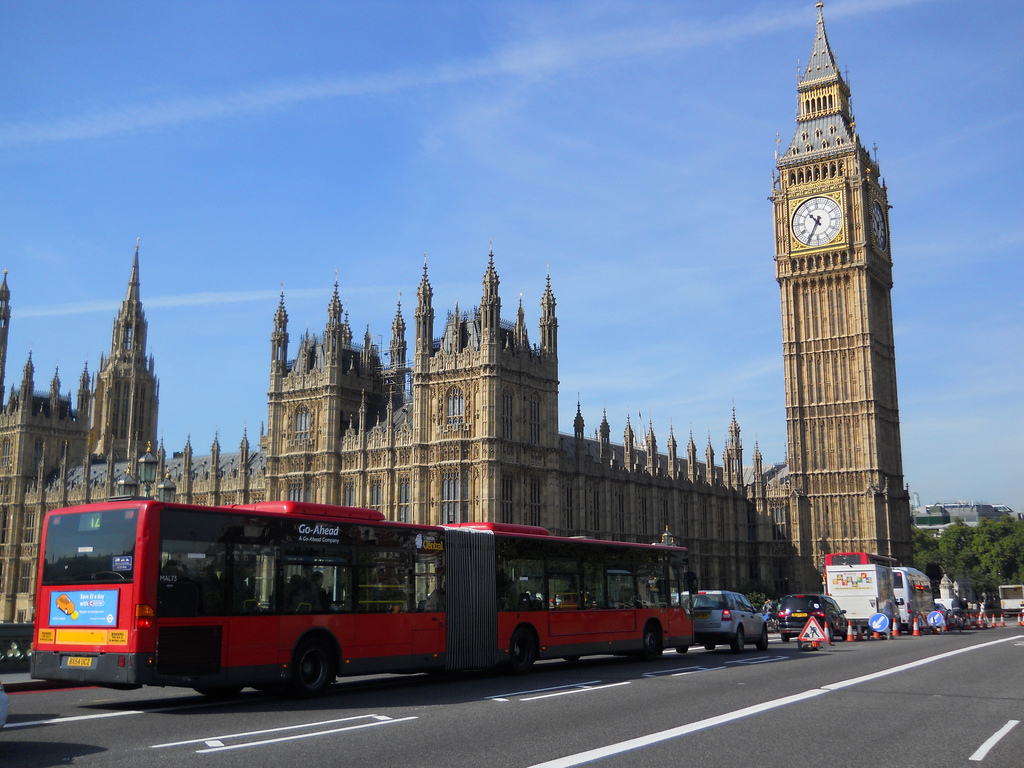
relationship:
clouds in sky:
[123, 80, 392, 164] [234, 124, 374, 213]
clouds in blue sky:
[6, 3, 1016, 500] [0, 0, 1024, 514]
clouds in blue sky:
[116, 65, 616, 202] [0, 0, 1024, 514]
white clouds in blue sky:
[396, 48, 665, 214] [5, 4, 287, 92]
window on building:
[496, 467, 517, 521] [1, 10, 922, 611]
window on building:
[487, 377, 516, 436] [1, 10, 922, 611]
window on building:
[385, 455, 418, 514] [1, 10, 922, 611]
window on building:
[360, 468, 383, 508] [1, 10, 922, 611]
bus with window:
[28, 499, 694, 696] [153, 512, 682, 646]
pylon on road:
[904, 613, 920, 642] [7, 609, 1013, 766]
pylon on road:
[886, 611, 903, 643] [7, 609, 1013, 766]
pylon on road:
[863, 614, 886, 649] [7, 609, 1013, 766]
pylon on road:
[835, 611, 867, 646] [7, 609, 1013, 766]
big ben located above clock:
[774, 4, 905, 567] [796, 185, 859, 263]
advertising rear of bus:
[39, 582, 131, 631] [28, 499, 694, 696]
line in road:
[951, 707, 1016, 766] [0, 621, 1024, 768]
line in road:
[546, 629, 1019, 766] [0, 621, 1024, 768]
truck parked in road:
[823, 543, 916, 624] [0, 621, 1024, 768]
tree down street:
[917, 496, 1022, 594] [0, 537, 1016, 766]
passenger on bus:
[273, 570, 302, 613] [28, 499, 694, 696]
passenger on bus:
[303, 566, 330, 611] [28, 499, 694, 696]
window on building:
[288, 451, 320, 489] [12, 238, 823, 768]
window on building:
[658, 491, 679, 537] [1, 10, 922, 611]